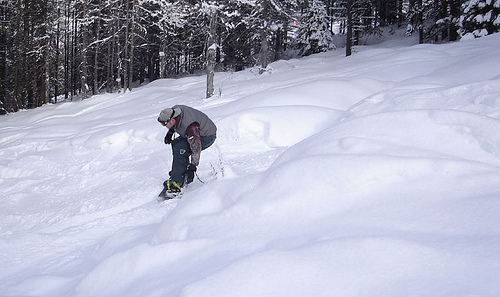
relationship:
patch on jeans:
[178, 146, 188, 157] [165, 135, 216, 187]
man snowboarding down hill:
[157, 104, 216, 187] [1, 23, 498, 295]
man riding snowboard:
[157, 104, 216, 187] [155, 192, 207, 208]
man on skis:
[157, 104, 216, 187] [159, 173, 189, 198]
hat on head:
[155, 102, 184, 129] [150, 101, 189, 136]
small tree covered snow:
[0, 0, 500, 115] [316, 8, 323, 19]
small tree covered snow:
[0, 0, 500, 115] [464, 6, 473, 12]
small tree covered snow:
[0, 0, 500, 115] [152, 7, 165, 18]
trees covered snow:
[68, 7, 115, 91] [68, 20, 85, 29]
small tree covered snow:
[0, 0, 500, 115] [35, 34, 49, 48]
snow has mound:
[0, 22, 496, 295] [295, 114, 384, 182]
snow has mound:
[0, 22, 496, 295] [243, 97, 329, 135]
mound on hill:
[295, 114, 384, 182] [159, 81, 491, 293]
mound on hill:
[243, 97, 329, 135] [159, 81, 491, 293]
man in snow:
[157, 104, 216, 187] [134, 96, 226, 214]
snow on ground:
[0, 0, 500, 295] [14, 240, 484, 295]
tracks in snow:
[40, 185, 169, 236] [40, 134, 233, 284]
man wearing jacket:
[157, 104, 216, 187] [172, 104, 217, 138]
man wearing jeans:
[157, 104, 216, 187] [169, 135, 216, 183]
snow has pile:
[0, 22, 496, 295] [206, 110, 320, 152]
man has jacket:
[157, 104, 216, 187] [166, 103, 218, 142]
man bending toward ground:
[168, 109, 240, 198] [124, 196, 218, 242]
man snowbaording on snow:
[157, 104, 216, 187] [142, 193, 461, 254]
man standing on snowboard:
[157, 104, 216, 187] [158, 175, 182, 198]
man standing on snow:
[157, 104, 216, 187] [244, 100, 489, 248]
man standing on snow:
[157, 104, 216, 187] [119, 193, 286, 233]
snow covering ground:
[0, 22, 496, 295] [3, 30, 497, 295]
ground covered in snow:
[10, 77, 492, 288] [1, 50, 484, 280]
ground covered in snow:
[10, 77, 492, 288] [22, 92, 490, 290]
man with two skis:
[157, 104, 216, 187] [159, 177, 191, 199]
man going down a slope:
[157, 104, 216, 187] [66, 195, 395, 226]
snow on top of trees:
[0, 0, 500, 295] [34, 50, 348, 57]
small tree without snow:
[23, 39, 40, 111] [0, 70, 32, 113]